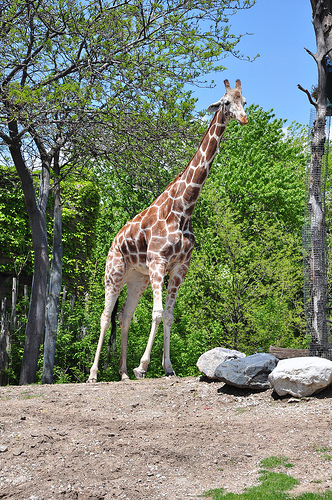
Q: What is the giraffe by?
A: Three stones.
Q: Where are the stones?
A: On the ground.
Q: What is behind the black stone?
A: A tree.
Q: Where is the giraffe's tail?
A: Between it's back legs.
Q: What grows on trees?
A: Leaves.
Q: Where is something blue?
A: The sky.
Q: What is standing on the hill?
A: The giraffe.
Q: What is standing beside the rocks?
A: The giraffe.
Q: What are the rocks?
A: Three similar shapes.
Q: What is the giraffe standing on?
A: The dirt.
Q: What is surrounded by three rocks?
A: The tree trunk.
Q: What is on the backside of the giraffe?
A: The trunk.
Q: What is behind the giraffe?
A: The wall of trees.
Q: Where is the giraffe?
A: The field.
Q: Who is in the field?
A: The giraffe.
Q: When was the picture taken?
A: Daytime.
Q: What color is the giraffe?
A: Brown and white.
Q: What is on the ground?
A: Dirt.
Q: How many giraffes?
A: 1.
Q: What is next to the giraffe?
A: Rocks.